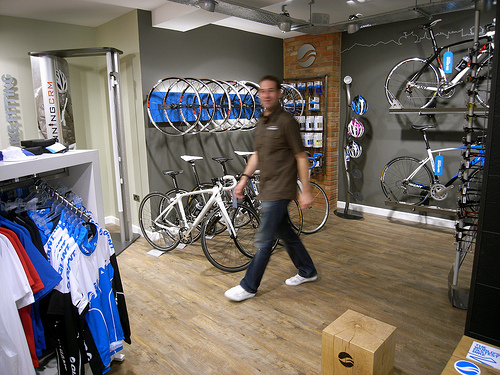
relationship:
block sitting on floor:
[321, 309, 399, 375] [112, 187, 476, 372]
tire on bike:
[377, 153, 434, 211] [379, 121, 486, 214]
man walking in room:
[226, 66, 324, 291] [2, 3, 496, 372]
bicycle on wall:
[384, 15, 496, 109] [346, 42, 401, 192]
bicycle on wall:
[378, 124, 489, 207] [346, 42, 401, 192]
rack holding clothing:
[32, 177, 102, 227] [0, 191, 133, 371]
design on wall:
[338, 14, 495, 49] [279, 20, 495, 225]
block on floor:
[321, 309, 399, 375] [112, 187, 476, 372]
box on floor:
[440, 333, 497, 375] [112, 187, 476, 372]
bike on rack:
[382, 17, 495, 107] [121, 85, 314, 320]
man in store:
[223, 73, 319, 302] [119, 15, 481, 346]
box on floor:
[440, 333, 499, 373] [78, 210, 498, 374]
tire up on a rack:
[145, 75, 201, 135] [14, 67, 90, 155]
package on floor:
[432, 333, 494, 370] [78, 210, 498, 374]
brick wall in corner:
[326, 35, 339, 190] [262, 34, 338, 212]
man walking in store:
[226, 66, 324, 291] [2, 4, 497, 351]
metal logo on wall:
[279, 41, 340, 201] [282, 29, 340, 213]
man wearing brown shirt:
[223, 73, 319, 302] [250, 110, 307, 202]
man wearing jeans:
[223, 73, 319, 302] [252, 200, 317, 292]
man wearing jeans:
[223, 73, 319, 302] [238, 200, 318, 294]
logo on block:
[336, 349, 354, 367] [321, 309, 422, 367]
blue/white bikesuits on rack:
[42, 205, 134, 365] [26, 172, 96, 235]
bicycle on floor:
[135, 170, 267, 278] [78, 210, 498, 374]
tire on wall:
[145, 75, 201, 135] [138, 10, 284, 241]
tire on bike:
[378, 154, 433, 210] [346, 114, 498, 212]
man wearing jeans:
[223, 73, 319, 302] [238, 188, 318, 295]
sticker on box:
[452, 356, 481, 373] [440, 333, 499, 373]